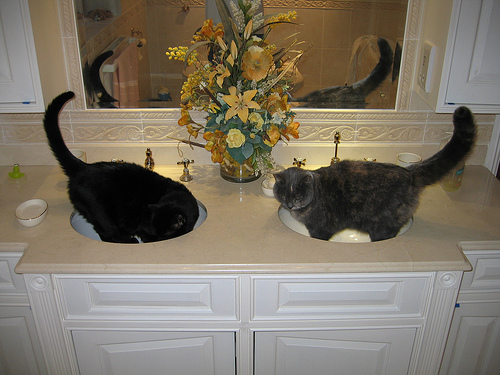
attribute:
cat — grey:
[277, 105, 490, 250]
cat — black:
[46, 98, 191, 237]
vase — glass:
[195, 125, 267, 193]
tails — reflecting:
[85, 46, 401, 96]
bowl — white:
[21, 207, 49, 226]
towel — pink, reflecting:
[118, 36, 144, 97]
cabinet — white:
[443, 2, 497, 107]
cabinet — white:
[62, 273, 420, 367]